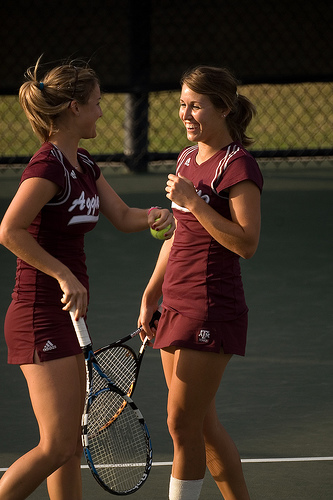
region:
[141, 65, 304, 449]
woman in tennis outfit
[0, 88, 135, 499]
woman in tennis outfit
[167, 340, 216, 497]
woman with white sock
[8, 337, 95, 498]
legs of tennis player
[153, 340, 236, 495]
legs of tennis player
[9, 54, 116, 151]
brown hair of tennis player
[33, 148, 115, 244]
white writing on brown uniform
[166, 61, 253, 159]
brown hair of woman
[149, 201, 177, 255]
green ball in players hand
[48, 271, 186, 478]
tennis racket of player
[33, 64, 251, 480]
two tennis player wearing red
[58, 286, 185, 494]
two tennis rackets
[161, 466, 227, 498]
tip of a white sock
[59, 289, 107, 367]
white handle of a tennis racket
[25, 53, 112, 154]
a blonde tennis player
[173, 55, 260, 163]
a brunette tennis player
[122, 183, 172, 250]
a woman holding a ball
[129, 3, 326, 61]
a black iron fence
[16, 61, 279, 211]
two women looking at each other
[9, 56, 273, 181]
two women smiling at each other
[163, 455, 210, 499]
white sock on woman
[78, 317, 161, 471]
two tennis rackets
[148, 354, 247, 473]
legs of the woman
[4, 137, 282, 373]
red outfits of women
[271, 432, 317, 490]
white line on court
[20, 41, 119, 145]
brown hair of girl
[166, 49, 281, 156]
woman with an earring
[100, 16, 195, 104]
fence behind the women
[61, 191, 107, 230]
white writing on jersey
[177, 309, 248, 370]
Woman wearing maroon skirt.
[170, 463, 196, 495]
White tape around leg.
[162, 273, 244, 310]
Woman wearing maroon top.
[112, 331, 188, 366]
Woman holding tennis racket.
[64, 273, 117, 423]
Woman holding tennis racket.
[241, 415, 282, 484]
White line on tennis court.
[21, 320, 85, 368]
Woman wearing maroon skirt.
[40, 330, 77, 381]
Adidas logo on skirt.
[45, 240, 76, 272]
Woman wearing maroon shirt.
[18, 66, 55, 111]
Blue rubber band in girl's hair.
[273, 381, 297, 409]
part of a court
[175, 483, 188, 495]
part of a sock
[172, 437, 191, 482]
part of a leg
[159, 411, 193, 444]
part of a knee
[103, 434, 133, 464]
part of a racket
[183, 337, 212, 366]
edge of a skirt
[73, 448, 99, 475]
edge of a racket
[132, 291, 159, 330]
part of a hand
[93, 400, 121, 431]
part of a racket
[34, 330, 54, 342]
part of a skirt